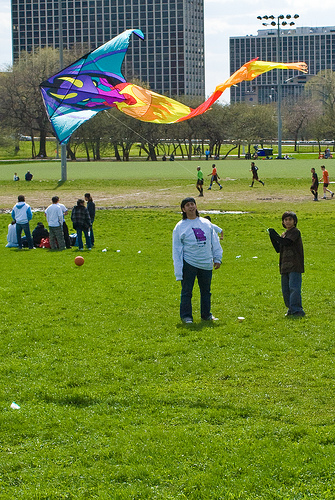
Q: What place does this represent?
A: It represents the park.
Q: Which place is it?
A: It is a park.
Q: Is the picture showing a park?
A: Yes, it is showing a park.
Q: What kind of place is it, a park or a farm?
A: It is a park.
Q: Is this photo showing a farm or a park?
A: It is showing a park.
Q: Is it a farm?
A: No, it is a park.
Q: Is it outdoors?
A: Yes, it is outdoors.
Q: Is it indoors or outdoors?
A: It is outdoors.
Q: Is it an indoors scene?
A: No, it is outdoors.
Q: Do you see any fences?
A: No, there are no fences.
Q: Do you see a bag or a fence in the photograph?
A: No, there are no fences or bags.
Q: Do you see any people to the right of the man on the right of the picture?
A: Yes, there are people to the right of the man.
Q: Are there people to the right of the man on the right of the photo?
A: Yes, there are people to the right of the man.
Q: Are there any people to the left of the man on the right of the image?
A: No, the people are to the right of the man.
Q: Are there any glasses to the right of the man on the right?
A: No, there are people to the right of the man.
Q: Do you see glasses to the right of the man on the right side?
A: No, there are people to the right of the man.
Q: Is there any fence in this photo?
A: No, there are no fences.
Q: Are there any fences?
A: No, there are no fences.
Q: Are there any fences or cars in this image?
A: No, there are no fences or cars.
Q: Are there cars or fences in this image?
A: No, there are no fences or cars.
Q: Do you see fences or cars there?
A: No, there are no fences or cars.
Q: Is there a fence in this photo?
A: No, there are no fences.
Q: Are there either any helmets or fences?
A: No, there are no fences or helmets.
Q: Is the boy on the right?
A: Yes, the boy is on the right of the image.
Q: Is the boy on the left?
A: No, the boy is on the right of the image.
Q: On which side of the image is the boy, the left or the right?
A: The boy is on the right of the image.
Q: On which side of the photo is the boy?
A: The boy is on the right of the image.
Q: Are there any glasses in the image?
A: No, there are no glasses.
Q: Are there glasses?
A: No, there are no glasses.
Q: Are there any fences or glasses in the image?
A: No, there are no glasses or fences.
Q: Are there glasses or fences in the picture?
A: No, there are no glasses or fences.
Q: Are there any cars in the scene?
A: No, there are no cars.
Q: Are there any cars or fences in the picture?
A: No, there are no cars or fences.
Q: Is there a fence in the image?
A: No, there are no fences.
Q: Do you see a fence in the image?
A: No, there are no fences.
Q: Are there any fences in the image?
A: No, there are no fences.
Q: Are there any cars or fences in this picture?
A: No, there are no fences or cars.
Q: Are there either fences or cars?
A: No, there are no fences or cars.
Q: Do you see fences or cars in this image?
A: No, there are no fences or cars.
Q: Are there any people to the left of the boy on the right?
A: Yes, there are people to the left of the boy.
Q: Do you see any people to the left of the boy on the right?
A: Yes, there are people to the left of the boy.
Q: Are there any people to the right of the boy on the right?
A: No, the people are to the left of the boy.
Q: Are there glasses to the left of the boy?
A: No, there are people to the left of the boy.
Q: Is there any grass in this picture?
A: Yes, there is grass.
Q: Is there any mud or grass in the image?
A: Yes, there is grass.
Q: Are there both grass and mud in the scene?
A: No, there is grass but no mud.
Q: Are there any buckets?
A: No, there are no buckets.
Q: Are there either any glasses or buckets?
A: No, there are no buckets or glasses.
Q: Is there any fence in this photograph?
A: No, there are no fences.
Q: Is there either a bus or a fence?
A: No, there are no fences or buses.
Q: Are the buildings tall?
A: Yes, the buildings are tall.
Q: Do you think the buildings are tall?
A: Yes, the buildings are tall.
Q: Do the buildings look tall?
A: Yes, the buildings are tall.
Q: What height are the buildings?
A: The buildings are tall.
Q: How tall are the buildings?
A: The buildings are tall.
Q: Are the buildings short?
A: No, the buildings are tall.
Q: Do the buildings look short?
A: No, the buildings are tall.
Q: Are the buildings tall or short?
A: The buildings are tall.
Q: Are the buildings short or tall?
A: The buildings are tall.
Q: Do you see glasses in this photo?
A: No, there are no glasses.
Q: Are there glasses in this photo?
A: No, there are no glasses.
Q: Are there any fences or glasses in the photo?
A: No, there are no glasses or fences.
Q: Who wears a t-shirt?
A: The man wears a t-shirt.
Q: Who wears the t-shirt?
A: The man wears a t-shirt.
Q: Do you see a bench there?
A: No, there are no benches.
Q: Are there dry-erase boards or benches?
A: No, there are no benches or dry-erase boards.